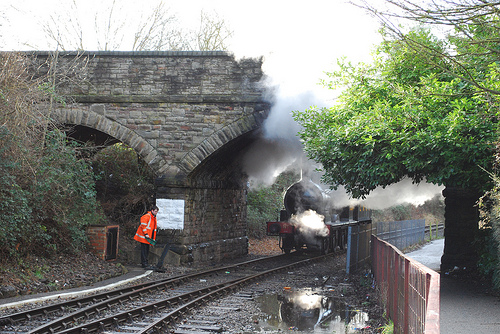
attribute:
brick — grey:
[128, 108, 147, 120]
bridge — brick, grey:
[1, 42, 302, 183]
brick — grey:
[242, 73, 265, 82]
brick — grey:
[207, 134, 220, 149]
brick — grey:
[170, 105, 186, 115]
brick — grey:
[202, 139, 214, 153]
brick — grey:
[129, 110, 141, 119]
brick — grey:
[119, 63, 130, 70]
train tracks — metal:
[0, 244, 329, 332]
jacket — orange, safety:
[88, 187, 196, 272]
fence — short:
[371, 232, 436, 332]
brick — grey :
[192, 142, 209, 162]